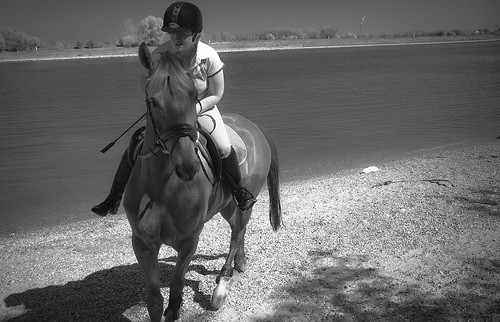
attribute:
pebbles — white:
[314, 168, 414, 203]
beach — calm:
[13, 178, 105, 278]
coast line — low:
[234, 26, 485, 67]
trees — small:
[119, 11, 165, 55]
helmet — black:
[150, 1, 211, 66]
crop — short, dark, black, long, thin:
[82, 108, 157, 146]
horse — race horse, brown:
[138, 65, 219, 272]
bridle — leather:
[145, 112, 210, 149]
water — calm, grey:
[287, 71, 416, 142]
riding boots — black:
[222, 142, 255, 202]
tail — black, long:
[257, 133, 292, 227]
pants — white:
[197, 102, 230, 163]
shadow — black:
[9, 251, 201, 314]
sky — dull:
[362, 16, 435, 33]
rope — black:
[128, 127, 149, 160]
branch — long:
[369, 178, 455, 192]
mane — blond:
[145, 34, 195, 103]